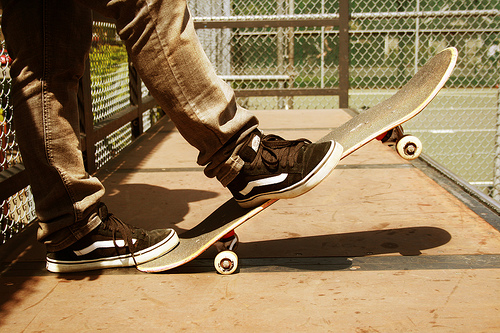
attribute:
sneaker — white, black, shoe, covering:
[229, 131, 338, 211]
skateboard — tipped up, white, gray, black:
[131, 44, 461, 276]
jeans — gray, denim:
[1, 2, 261, 251]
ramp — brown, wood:
[4, 102, 499, 328]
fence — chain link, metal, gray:
[188, 1, 498, 127]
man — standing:
[0, 1, 346, 314]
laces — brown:
[250, 134, 313, 171]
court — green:
[269, 87, 499, 180]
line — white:
[402, 124, 499, 137]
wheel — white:
[392, 134, 424, 161]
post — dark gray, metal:
[186, 7, 499, 21]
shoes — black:
[38, 130, 346, 281]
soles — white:
[46, 230, 177, 273]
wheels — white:
[211, 230, 244, 277]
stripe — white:
[235, 174, 286, 196]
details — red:
[224, 231, 233, 244]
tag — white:
[247, 133, 263, 153]